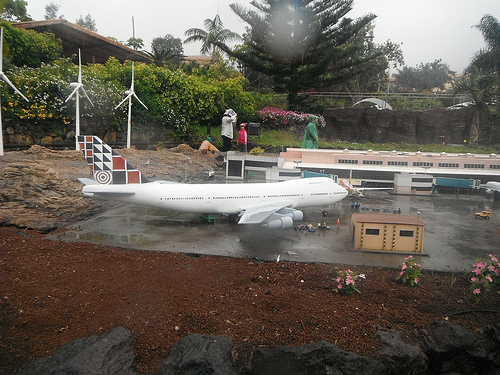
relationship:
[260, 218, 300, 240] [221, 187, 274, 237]
engine under wing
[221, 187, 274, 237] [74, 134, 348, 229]
wing of airplane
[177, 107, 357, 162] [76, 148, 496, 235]
people behind airport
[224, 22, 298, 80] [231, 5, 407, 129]
leaves of tree